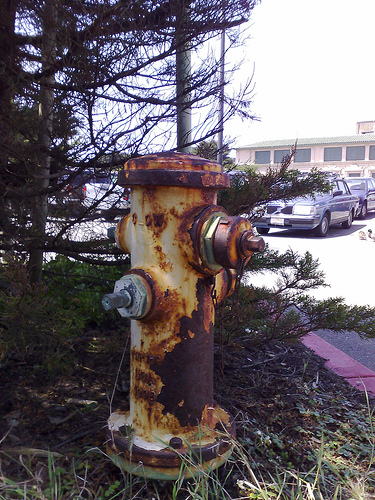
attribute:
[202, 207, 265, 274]
valve — large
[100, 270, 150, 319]
valve — large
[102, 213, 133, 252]
valve — large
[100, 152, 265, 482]
rusted hydrant — old 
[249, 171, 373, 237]
cars — parked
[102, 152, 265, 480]
hydrant — rusted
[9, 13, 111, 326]
tree — evergreen 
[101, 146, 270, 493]
fire hydrant — old, rusted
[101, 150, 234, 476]
hydrant — old 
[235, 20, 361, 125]
sky — grey, hazy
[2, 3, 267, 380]
tree — tall, pine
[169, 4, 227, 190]
poles — light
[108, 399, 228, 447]
bolts — rusted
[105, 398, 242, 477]
base — rusted